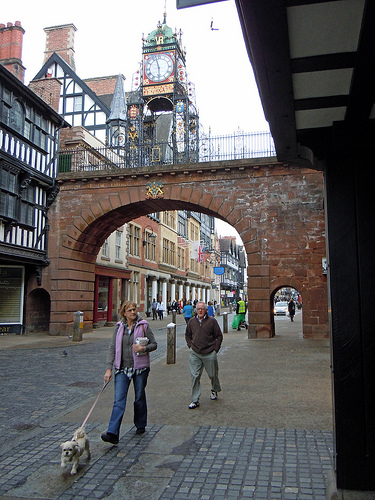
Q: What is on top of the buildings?
A: Chimneys.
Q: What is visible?
A: The dog.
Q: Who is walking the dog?
A: The woman.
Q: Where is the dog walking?
A: On the side of the street.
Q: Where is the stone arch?
A: Over the street.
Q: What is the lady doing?
A: Walking a dog.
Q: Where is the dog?
A: On the ground.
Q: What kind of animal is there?
A: Dog.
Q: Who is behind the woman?
A: A man.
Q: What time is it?
A: Afternoon.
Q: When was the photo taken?
A: During the daytime.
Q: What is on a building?
A: A clock.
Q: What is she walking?
A: Dog.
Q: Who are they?
A: People.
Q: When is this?
A: Daytime.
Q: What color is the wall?
A: Brown.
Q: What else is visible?
A: Buildings.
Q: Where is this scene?
A: On a city sidewalk.